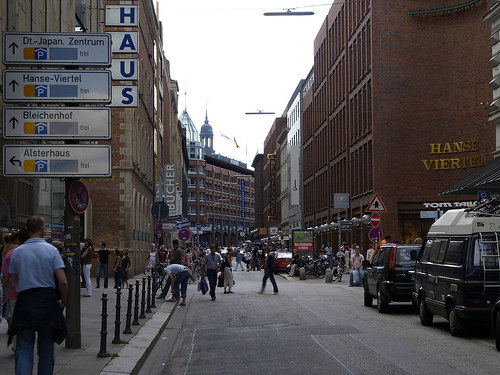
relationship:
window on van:
[448, 237, 471, 263] [412, 208, 497, 331]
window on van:
[422, 235, 443, 260] [412, 208, 497, 331]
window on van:
[470, 239, 480, 266] [412, 208, 497, 331]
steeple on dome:
[204, 104, 209, 124] [197, 123, 216, 148]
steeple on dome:
[201, 103, 218, 136] [201, 118, 221, 152]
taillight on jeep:
[385, 245, 399, 272] [366, 248, 416, 310]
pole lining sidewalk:
[96, 292, 109, 357] [56, 277, 136, 357]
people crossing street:
[217, 248, 278, 295] [156, 271, 364, 298]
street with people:
[119, 235, 491, 374] [116, 217, 325, 312]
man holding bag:
[342, 242, 367, 288] [349, 267, 362, 284]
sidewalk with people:
[30, 273, 179, 374] [70, 229, 136, 307]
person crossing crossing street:
[257, 246, 280, 297] [142, 244, 496, 371]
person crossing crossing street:
[221, 247, 235, 294] [142, 244, 496, 371]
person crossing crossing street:
[249, 244, 261, 272] [142, 244, 496, 371]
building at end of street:
[169, 160, 289, 215] [168, 257, 463, 364]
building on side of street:
[0, 0, 500, 288] [142, 244, 496, 371]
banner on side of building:
[159, 160, 185, 220] [48, 45, 191, 273]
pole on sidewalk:
[90, 290, 112, 361] [53, 274, 153, 372]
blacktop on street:
[185, 317, 385, 374] [135, 260, 495, 372]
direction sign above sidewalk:
[3, 144, 112, 179] [0, 270, 169, 374]